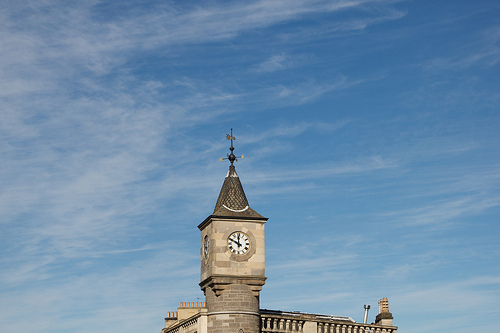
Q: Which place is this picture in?
A: It is at the church.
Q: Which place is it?
A: It is a church.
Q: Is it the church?
A: Yes, it is the church.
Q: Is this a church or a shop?
A: It is a church.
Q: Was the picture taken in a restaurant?
A: No, the picture was taken in a church.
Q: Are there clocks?
A: Yes, there is a clock.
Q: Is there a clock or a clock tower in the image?
A: Yes, there is a clock.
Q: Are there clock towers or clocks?
A: Yes, there is a clock.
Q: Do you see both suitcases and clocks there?
A: No, there is a clock but no suitcases.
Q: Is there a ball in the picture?
A: No, there are no balls.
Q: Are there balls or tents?
A: No, there are no balls or tents.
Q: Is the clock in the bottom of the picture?
A: Yes, the clock is in the bottom of the image.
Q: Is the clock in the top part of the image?
A: No, the clock is in the bottom of the image.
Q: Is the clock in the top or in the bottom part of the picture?
A: The clock is in the bottom of the image.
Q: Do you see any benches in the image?
A: No, there are no benches.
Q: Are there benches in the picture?
A: No, there are no benches.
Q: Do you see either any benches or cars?
A: No, there are no benches or cars.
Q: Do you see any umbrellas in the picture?
A: No, there are no umbrellas.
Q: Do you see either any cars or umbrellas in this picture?
A: No, there are no umbrellas or cars.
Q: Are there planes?
A: No, there are no planes.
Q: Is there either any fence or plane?
A: No, there are no airplanes or fences.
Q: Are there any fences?
A: No, there are no fences.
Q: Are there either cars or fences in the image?
A: No, there are no fences or cars.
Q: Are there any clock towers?
A: Yes, there is a clock tower.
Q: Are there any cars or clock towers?
A: Yes, there is a clock tower.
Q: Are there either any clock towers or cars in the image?
A: Yes, there is a clock tower.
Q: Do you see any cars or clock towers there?
A: Yes, there is a clock tower.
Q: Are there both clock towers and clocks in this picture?
A: Yes, there are both a clock tower and a clock.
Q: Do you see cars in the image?
A: No, there are no cars.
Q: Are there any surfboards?
A: No, there are no surfboards.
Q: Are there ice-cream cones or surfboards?
A: No, there are no surfboards or ice-cream cones.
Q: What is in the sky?
A: The clouds are in the sky.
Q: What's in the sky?
A: The clouds are in the sky.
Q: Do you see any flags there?
A: No, there are no flags.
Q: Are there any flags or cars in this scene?
A: No, there are no flags or cars.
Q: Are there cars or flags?
A: No, there are no flags or cars.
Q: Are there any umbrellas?
A: No, there are no umbrellas.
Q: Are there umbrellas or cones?
A: No, there are no umbrellas or cones.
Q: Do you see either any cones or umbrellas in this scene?
A: No, there are no umbrellas or cones.